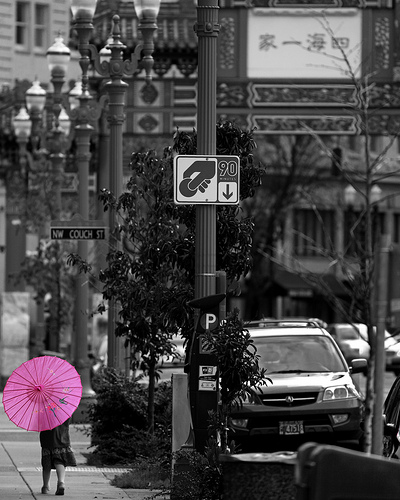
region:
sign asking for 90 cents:
[170, 152, 243, 211]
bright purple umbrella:
[1, 352, 88, 442]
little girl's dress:
[36, 429, 79, 489]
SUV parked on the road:
[211, 314, 368, 463]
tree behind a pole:
[106, 116, 233, 483]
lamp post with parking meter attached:
[184, 0, 240, 468]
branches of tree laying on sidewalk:
[99, 370, 217, 498]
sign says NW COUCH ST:
[49, 221, 113, 249]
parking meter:
[183, 276, 237, 469]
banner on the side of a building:
[241, 8, 377, 88]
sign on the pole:
[134, 142, 251, 216]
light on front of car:
[302, 362, 364, 418]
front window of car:
[227, 323, 353, 390]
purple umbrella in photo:
[2, 345, 100, 418]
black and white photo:
[180, 198, 352, 384]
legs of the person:
[22, 454, 80, 499]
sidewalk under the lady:
[84, 465, 123, 499]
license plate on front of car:
[268, 411, 324, 446]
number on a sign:
[202, 147, 254, 187]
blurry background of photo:
[258, 141, 373, 276]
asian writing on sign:
[229, 2, 393, 96]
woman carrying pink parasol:
[1, 344, 93, 499]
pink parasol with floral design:
[0, 350, 78, 449]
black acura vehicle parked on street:
[221, 322, 365, 452]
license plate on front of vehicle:
[276, 414, 312, 449]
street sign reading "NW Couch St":
[41, 220, 123, 254]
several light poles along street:
[3, 7, 192, 470]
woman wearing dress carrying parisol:
[5, 346, 98, 496]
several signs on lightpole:
[187, 261, 230, 416]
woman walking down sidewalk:
[5, 350, 97, 495]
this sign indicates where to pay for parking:
[172, 152, 242, 207]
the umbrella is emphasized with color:
[1, 355, 87, 435]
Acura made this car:
[202, 316, 365, 453]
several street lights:
[14, 0, 224, 492]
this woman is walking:
[37, 379, 75, 496]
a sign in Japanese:
[242, 5, 364, 80]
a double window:
[11, 1, 51, 55]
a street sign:
[48, 224, 110, 242]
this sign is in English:
[48, 225, 108, 242]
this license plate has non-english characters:
[277, 419, 307, 436]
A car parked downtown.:
[217, 317, 370, 450]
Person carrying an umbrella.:
[3, 355, 77, 497]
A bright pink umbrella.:
[2, 355, 83, 432]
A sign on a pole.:
[168, 153, 242, 205]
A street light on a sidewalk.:
[10, 91, 106, 421]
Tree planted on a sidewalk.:
[108, 120, 271, 492]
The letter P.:
[199, 301, 221, 330]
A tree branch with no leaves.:
[305, 11, 387, 140]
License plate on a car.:
[276, 419, 306, 435]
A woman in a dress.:
[5, 354, 82, 499]